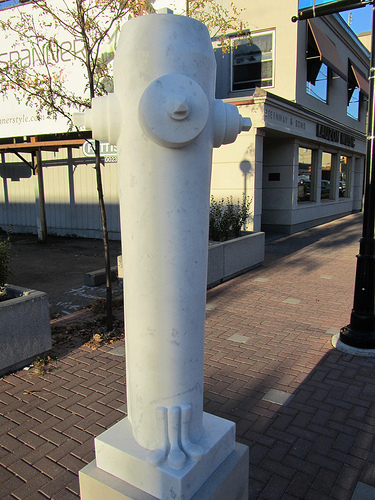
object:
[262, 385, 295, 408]
brick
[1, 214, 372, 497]
sidewalk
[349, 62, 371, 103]
awnings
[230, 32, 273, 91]
window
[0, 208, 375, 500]
floor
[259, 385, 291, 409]
brick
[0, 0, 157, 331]
tree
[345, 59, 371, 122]
window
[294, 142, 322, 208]
window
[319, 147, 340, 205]
window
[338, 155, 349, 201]
window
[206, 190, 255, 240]
plants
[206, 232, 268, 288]
concrete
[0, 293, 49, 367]
concrete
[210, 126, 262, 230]
concrete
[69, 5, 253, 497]
concrete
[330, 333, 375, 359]
concrete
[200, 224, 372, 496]
tile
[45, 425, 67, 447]
brick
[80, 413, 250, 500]
base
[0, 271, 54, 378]
planter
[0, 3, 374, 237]
building